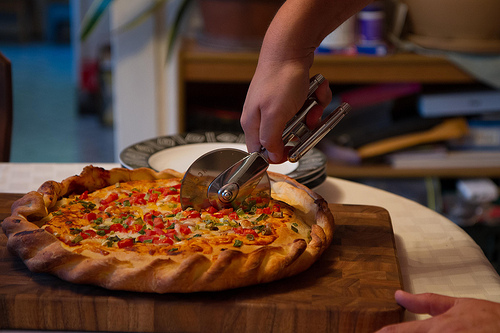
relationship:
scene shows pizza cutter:
[4, 2, 500, 329] [178, 96, 321, 213]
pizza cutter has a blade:
[178, 96, 321, 213] [174, 148, 281, 209]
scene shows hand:
[4, 2, 500, 329] [233, 62, 331, 163]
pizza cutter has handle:
[178, 96, 321, 213] [253, 77, 348, 161]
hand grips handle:
[233, 62, 331, 163] [253, 77, 348, 161]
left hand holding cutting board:
[378, 288, 500, 333] [1, 196, 407, 333]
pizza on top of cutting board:
[10, 167, 337, 296] [1, 196, 407, 333]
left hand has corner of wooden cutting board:
[378, 288, 500, 333] [1, 196, 407, 333]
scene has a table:
[4, 2, 500, 329] [3, 158, 500, 299]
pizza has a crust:
[10, 167, 337, 296] [46, 248, 246, 291]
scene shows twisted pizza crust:
[4, 2, 500, 329] [46, 248, 246, 291]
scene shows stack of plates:
[4, 2, 500, 329] [111, 135, 332, 188]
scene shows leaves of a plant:
[4, 2, 500, 329] [79, 1, 204, 65]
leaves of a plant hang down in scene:
[79, 1, 204, 65] [4, 2, 500, 329]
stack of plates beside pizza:
[111, 135, 332, 188] [10, 167, 337, 296]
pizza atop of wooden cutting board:
[10, 167, 337, 296] [1, 196, 407, 333]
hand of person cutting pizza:
[233, 62, 331, 163] [10, 167, 337, 296]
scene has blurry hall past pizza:
[4, 2, 500, 329] [10, 167, 337, 296]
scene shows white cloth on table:
[4, 2, 500, 329] [3, 158, 500, 299]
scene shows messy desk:
[4, 2, 500, 329] [179, 40, 481, 138]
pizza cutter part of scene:
[178, 96, 321, 213] [4, 2, 500, 329]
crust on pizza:
[46, 248, 246, 291] [10, 167, 337, 296]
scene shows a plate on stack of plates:
[4, 2, 500, 329] [111, 135, 332, 188]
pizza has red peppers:
[10, 167, 337, 296] [146, 216, 191, 244]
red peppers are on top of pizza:
[146, 216, 191, 244] [10, 167, 337, 296]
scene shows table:
[4, 2, 500, 329] [3, 158, 500, 299]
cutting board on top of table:
[1, 196, 407, 333] [3, 158, 500, 299]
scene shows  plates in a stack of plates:
[4, 2, 500, 329] [111, 135, 332, 188]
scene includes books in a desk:
[4, 2, 500, 329] [179, 40, 481, 138]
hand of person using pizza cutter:
[233, 62, 331, 163] [178, 96, 321, 213]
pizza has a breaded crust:
[10, 167, 337, 296] [46, 248, 246, 291]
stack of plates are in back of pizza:
[111, 135, 332, 188] [10, 167, 337, 296]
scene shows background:
[4, 2, 500, 329] [5, 1, 499, 172]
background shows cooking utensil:
[5, 1, 499, 172] [359, 121, 467, 156]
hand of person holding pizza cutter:
[233, 62, 331, 163] [178, 96, 321, 213]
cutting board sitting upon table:
[1, 196, 407, 333] [3, 158, 500, 299]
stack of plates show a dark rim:
[111, 135, 332, 188] [294, 149, 325, 187]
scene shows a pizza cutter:
[4, 2, 500, 329] [178, 96, 321, 213]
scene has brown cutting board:
[4, 2, 500, 329] [1, 196, 407, 333]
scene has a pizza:
[4, 2, 500, 329] [10, 167, 337, 296]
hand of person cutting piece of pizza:
[233, 62, 331, 163] [10, 167, 337, 296]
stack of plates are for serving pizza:
[111, 135, 332, 188] [10, 167, 337, 296]